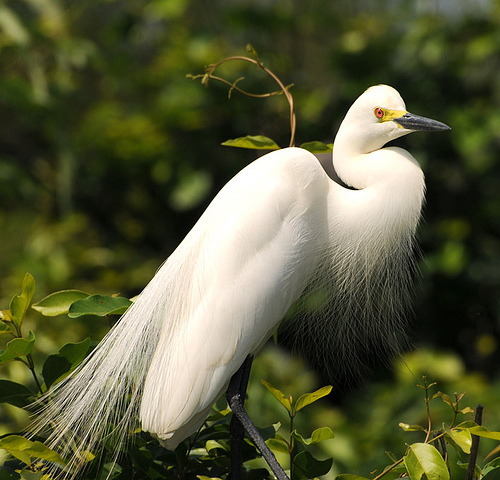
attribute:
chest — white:
[263, 178, 335, 307]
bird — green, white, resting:
[23, 82, 450, 480]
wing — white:
[140, 229, 252, 441]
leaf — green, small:
[32, 289, 88, 315]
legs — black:
[229, 356, 290, 480]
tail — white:
[18, 289, 162, 480]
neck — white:
[278, 140, 421, 392]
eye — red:
[372, 106, 385, 118]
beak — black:
[397, 112, 451, 139]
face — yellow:
[382, 109, 405, 130]